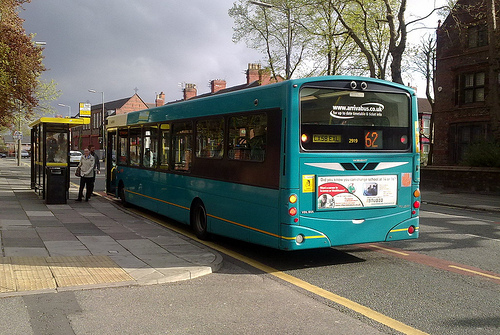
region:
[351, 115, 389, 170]
bus with the number 62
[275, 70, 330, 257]
teal bus driving down the street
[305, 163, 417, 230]
ad on the back of a bus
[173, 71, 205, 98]
spikes on the top of a building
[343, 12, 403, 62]
tree next to a buiolding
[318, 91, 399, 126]
website on the back of the bus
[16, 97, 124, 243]
bus stop on the side of the street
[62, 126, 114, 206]
people getting off the bus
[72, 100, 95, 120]
yellow sign on the bus stop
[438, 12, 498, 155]
red brick building on the side of the road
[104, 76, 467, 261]
a bus on the street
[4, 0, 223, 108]
a dark and grey sky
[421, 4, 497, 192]
an old brick building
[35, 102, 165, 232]
people at bus stop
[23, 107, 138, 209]
bus stop waiting area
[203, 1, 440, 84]
trees clustered against sky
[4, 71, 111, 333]
city sidewalk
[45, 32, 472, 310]
bus dropping people off at stop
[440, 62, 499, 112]
window on old brick building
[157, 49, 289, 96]
brick chimneys against sky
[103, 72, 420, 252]
Turquoise colored passenger bus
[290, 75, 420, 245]
Back of turquoise passenger bus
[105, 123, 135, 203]
Passenger entrance/exit door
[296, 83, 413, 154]
Back windshield of turquoise bus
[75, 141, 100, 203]
Man standing beside turquoise bus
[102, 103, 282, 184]
Passenger windows of turquoise bus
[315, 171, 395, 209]
Advertisement on back of turquoise bus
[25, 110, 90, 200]
Yellow and black passenger bus shelter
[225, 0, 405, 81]
Tall trees in the distance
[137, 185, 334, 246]
Yellow strip down left side of turquoise bus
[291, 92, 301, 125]
edge of a bus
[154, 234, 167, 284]
part of a pavement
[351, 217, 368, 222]
back of a bus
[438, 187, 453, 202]
edge of a road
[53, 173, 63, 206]
part of a bus stop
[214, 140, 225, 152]
part of a window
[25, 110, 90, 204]
a yellow and black bus shelter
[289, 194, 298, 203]
a bus's taillight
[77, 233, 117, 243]
a section of a concrete sidewalk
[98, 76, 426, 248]
a long green bus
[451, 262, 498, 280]
a yellow street marking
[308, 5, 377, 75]
a tall tree branch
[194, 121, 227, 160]
the window of a bus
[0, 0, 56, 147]
brown and green tree leaves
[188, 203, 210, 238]
a bus's tire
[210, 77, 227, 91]
a brick chimney